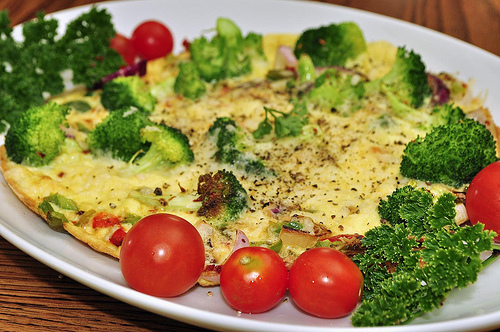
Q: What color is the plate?
A: White.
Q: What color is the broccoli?
A: Green.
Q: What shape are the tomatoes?
A: Round.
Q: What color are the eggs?
A: Yellow.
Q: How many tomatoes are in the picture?
A: Six.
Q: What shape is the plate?
A: Oval.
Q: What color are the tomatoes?
A: Red.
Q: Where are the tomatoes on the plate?
A: Near the edge.